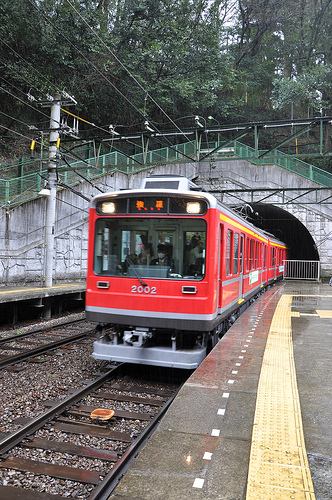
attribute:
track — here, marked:
[13, 333, 190, 498]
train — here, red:
[79, 178, 326, 361]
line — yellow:
[232, 254, 315, 488]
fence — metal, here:
[265, 246, 312, 285]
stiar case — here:
[16, 111, 123, 206]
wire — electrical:
[61, 27, 214, 148]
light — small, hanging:
[96, 199, 126, 229]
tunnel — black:
[232, 178, 330, 262]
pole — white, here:
[37, 71, 70, 283]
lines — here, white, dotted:
[181, 345, 264, 488]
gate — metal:
[287, 245, 328, 314]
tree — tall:
[130, 43, 258, 123]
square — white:
[207, 425, 226, 443]